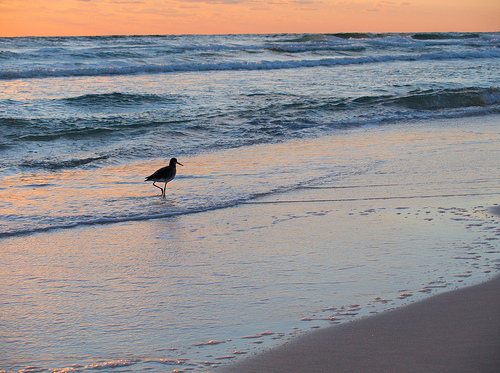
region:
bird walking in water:
[139, 154, 199, 203]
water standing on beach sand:
[164, 232, 362, 308]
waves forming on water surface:
[62, 27, 204, 74]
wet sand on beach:
[394, 319, 496, 371]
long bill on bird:
[175, 157, 189, 170]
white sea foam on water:
[94, 349, 193, 371]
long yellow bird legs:
[150, 178, 174, 201]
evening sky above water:
[3, 0, 215, 34]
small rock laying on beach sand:
[364, 324, 383, 344]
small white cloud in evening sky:
[132, 4, 195, 19]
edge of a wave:
[273, 106, 326, 153]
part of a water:
[250, 234, 283, 278]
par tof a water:
[343, 288, 372, 315]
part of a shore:
[416, 318, 445, 355]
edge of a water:
[269, 177, 310, 217]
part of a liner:
[272, 251, 303, 298]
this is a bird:
[147, 152, 189, 204]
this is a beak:
[177, 160, 188, 168]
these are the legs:
[149, 178, 174, 200]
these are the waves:
[297, 29, 377, 114]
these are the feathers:
[148, 164, 174, 182]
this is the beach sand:
[364, 295, 456, 366]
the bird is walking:
[140, 150, 188, 201]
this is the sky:
[224, 2, 261, 27]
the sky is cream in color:
[197, 2, 236, 30]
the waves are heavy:
[289, 32, 346, 67]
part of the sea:
[256, 230, 285, 260]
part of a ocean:
[390, 319, 396, 326]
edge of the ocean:
[353, 287, 375, 323]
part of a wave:
[301, 292, 306, 302]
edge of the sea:
[287, 206, 304, 224]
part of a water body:
[321, 337, 337, 358]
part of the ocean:
[289, 237, 301, 257]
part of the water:
[208, 184, 217, 212]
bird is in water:
[113, 139, 218, 234]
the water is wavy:
[83, 48, 272, 142]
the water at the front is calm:
[195, 277, 340, 327]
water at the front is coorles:
[138, 261, 274, 339]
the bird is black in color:
[143, 158, 202, 199]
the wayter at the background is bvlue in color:
[243, 94, 344, 131]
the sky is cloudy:
[148, 4, 249, 29]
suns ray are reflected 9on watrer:
[96, 32, 213, 108]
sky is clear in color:
[325, 1, 380, 14]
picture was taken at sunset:
[68, 40, 375, 283]